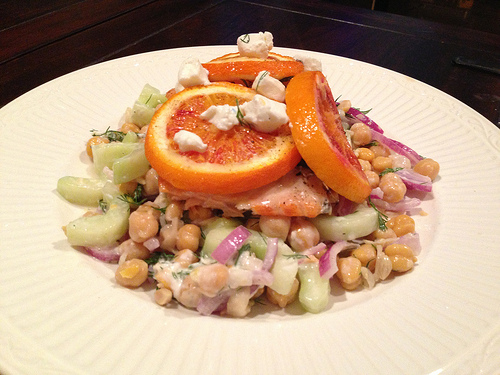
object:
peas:
[332, 244, 420, 279]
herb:
[117, 184, 149, 205]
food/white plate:
[0, 31, 499, 374]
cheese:
[173, 130, 208, 154]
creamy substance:
[152, 259, 188, 295]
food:
[55, 31, 442, 317]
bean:
[124, 205, 161, 242]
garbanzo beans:
[384, 242, 418, 272]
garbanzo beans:
[378, 172, 407, 203]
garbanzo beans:
[371, 155, 392, 172]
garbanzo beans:
[412, 157, 441, 181]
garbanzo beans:
[351, 242, 378, 272]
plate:
[0, 31, 499, 374]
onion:
[369, 128, 423, 165]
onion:
[210, 225, 251, 266]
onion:
[319, 240, 361, 281]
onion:
[83, 246, 120, 262]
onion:
[395, 169, 432, 192]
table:
[0, 2, 500, 129]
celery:
[65, 180, 130, 248]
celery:
[111, 143, 150, 186]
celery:
[56, 175, 102, 207]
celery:
[313, 205, 380, 242]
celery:
[297, 263, 331, 313]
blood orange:
[285, 68, 372, 205]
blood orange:
[144, 81, 301, 193]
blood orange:
[201, 51, 304, 81]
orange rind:
[161, 165, 250, 193]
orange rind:
[290, 91, 314, 140]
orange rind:
[201, 61, 303, 77]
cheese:
[236, 31, 274, 59]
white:
[239, 94, 290, 132]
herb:
[236, 98, 252, 130]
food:
[49, 63, 433, 331]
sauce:
[170, 165, 332, 218]